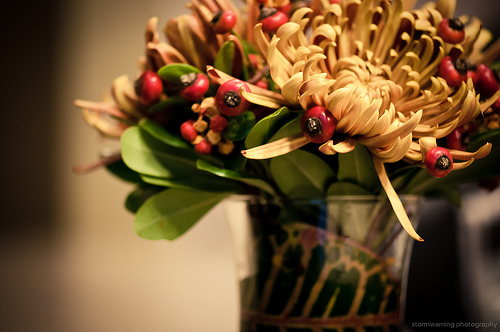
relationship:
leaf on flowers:
[132, 193, 219, 243] [77, 0, 483, 245]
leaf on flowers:
[121, 131, 190, 175] [77, 0, 483, 245]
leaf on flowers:
[136, 111, 192, 147] [77, 0, 483, 245]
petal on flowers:
[280, 23, 294, 64] [77, 0, 483, 245]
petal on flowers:
[247, 24, 270, 55] [77, 0, 483, 245]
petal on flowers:
[261, 35, 281, 75] [77, 0, 483, 245]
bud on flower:
[302, 105, 333, 141] [75, 4, 480, 240]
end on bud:
[221, 91, 238, 108] [214, 82, 245, 116]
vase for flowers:
[222, 190, 420, 330] [77, 0, 483, 245]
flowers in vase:
[77, 0, 483, 245] [222, 190, 420, 330]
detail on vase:
[250, 228, 397, 315] [222, 190, 420, 330]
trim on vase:
[303, 252, 331, 318] [222, 190, 420, 330]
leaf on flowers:
[132, 193, 220, 238] [77, 0, 483, 245]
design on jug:
[246, 240, 397, 320] [219, 195, 427, 329]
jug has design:
[219, 195, 427, 329] [246, 240, 397, 320]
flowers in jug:
[77, 0, 500, 246] [220, 179, 432, 315]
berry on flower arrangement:
[301, 108, 338, 143] [101, 29, 470, 225]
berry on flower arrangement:
[424, 145, 455, 178] [86, 41, 480, 210]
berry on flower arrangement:
[432, 55, 480, 85] [101, 29, 470, 225]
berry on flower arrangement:
[456, 48, 496, 110] [110, 45, 493, 225]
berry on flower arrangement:
[440, 17, 469, 45] [85, 33, 462, 218]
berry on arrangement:
[257, 10, 291, 32] [67, 1, 499, 239]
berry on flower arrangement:
[200, 12, 250, 32] [85, 33, 462, 218]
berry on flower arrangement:
[118, 63, 181, 114] [82, 42, 499, 180]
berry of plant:
[216, 78, 248, 115] [86, 39, 459, 209]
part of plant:
[115, 61, 181, 114] [91, 33, 453, 197]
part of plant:
[170, 70, 218, 112] [85, 31, 450, 224]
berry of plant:
[200, 12, 250, 32] [85, 31, 450, 224]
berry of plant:
[424, 145, 455, 178] [85, 31, 450, 224]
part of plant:
[431, 47, 469, 85] [113, 37, 453, 219]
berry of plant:
[440, 17, 469, 45] [113, 20, 434, 197]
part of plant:
[461, 50, 493, 95] [116, 36, 496, 226]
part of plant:
[457, 61, 480, 88] [101, 10, 466, 203]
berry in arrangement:
[419, 135, 465, 181] [83, 30, 455, 210]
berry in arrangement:
[301, 108, 335, 154] [102, 33, 472, 183]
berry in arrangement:
[440, 55, 471, 86] [108, 34, 461, 207]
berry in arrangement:
[475, 65, 500, 93] [67, 1, 482, 238]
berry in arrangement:
[430, 14, 469, 49] [67, 1, 482, 238]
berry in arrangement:
[250, 5, 291, 34] [67, 1, 482, 238]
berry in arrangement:
[200, 12, 250, 32] [67, 1, 482, 238]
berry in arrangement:
[135, 69, 164, 107] [67, 1, 482, 238]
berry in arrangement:
[169, 69, 212, 102] [67, 1, 482, 238]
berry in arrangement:
[204, 78, 249, 122] [67, 1, 482, 238]